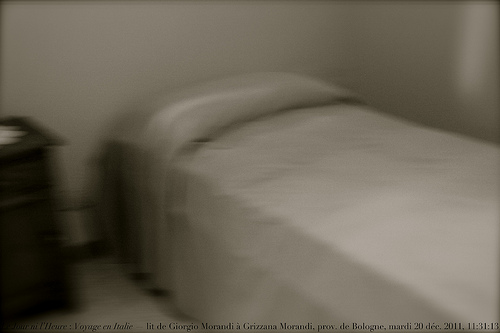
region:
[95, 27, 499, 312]
A bed is in this room.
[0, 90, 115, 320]
A dresser is next to the bed.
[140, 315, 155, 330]
The text says lit.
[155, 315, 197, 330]
The text says de Giorgio.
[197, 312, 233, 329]
The text says Morandi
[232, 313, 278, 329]
The text says a Grizzana.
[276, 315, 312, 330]
The text says Morandi.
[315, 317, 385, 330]
The text says prov. de Bologne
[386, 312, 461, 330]
The text says mardi 20 dec. 2011.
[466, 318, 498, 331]
The text says 11:31:13.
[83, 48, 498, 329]
a blurry bed photo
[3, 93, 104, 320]
a blurry brown desk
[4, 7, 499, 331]
a small desk and bed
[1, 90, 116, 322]
a small wooden nightstand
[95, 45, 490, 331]
a twin sized bed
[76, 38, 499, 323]
a blurry made bed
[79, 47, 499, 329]
a bed with folded sheets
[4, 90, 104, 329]
a small wooden stand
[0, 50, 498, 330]
a small, blurry bedroom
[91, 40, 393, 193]
a blurry photo of pillows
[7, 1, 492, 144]
The wall is white.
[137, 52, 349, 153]
Pillows on the bed.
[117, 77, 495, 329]
The sheets are white.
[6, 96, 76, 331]
The desk is brown.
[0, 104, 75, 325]
The desk is next to the bed.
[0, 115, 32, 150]
The papers are white.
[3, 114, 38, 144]
Papers on the table.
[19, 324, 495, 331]
The text is black.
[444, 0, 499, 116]
Light is shining on the wall.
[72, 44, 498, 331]
The bed is in the bedroom.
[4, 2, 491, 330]
the picture is blurry.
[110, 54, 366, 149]
Pillow on the bed.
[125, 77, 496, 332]
Bed sheets are white.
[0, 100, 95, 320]
The dresser is brown.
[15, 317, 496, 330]
The text is black.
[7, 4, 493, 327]
Bed in a bedroom.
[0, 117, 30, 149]
Papers on the desk.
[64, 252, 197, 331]
the ground is white.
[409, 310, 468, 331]
The date is December 20, 2011.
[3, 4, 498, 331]
Black and white filter.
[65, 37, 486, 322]
blurry picture of a bed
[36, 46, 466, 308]
blurry image of a bed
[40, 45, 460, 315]
blurry view of a bed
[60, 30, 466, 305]
blurry picture of bed with white sheets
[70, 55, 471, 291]
blurry image of bed with white sheets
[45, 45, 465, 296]
blurry view of bed with white sheets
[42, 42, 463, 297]
unfocused picture of bed with white sheets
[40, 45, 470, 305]
unfocused image of bed with white sheets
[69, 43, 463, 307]
bed view out of focus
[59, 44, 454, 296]
blurry bed with white sheets